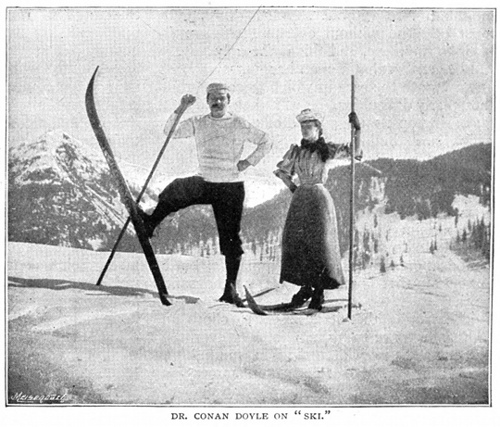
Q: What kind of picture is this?
A: Black and white.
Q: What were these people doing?
A: Skiing.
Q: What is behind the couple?
A: Mountain.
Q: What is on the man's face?
A: Mustache.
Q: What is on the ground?
A: Snow.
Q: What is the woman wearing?
A: Skirt.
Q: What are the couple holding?
A: Ski poles.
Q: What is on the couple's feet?
A: Skis.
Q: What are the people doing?
A: Skiing.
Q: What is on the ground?
A: Snow.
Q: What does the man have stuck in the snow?
A: His skis.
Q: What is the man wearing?
A: A white sweater.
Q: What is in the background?
A: Mountains.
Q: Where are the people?
A: In the mountains.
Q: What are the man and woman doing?
A: Skiing in the mountains.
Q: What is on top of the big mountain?
A: Snow.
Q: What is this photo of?
A: Man and woman.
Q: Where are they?
A: Ski slope.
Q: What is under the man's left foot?
A: Ski.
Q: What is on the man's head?
A: A small cap.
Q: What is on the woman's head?
A: A small hat.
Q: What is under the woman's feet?
A: Skis.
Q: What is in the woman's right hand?
A: A pole.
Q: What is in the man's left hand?
A: A fishing pole.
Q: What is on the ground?
A: Snow.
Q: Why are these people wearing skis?
A: To ski.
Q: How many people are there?
A: Two.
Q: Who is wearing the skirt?
A: The woman.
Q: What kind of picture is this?
A: Black and white.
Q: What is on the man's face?
A: A moustache.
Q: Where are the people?
A: Outdoors.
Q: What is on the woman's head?
A: A hat.